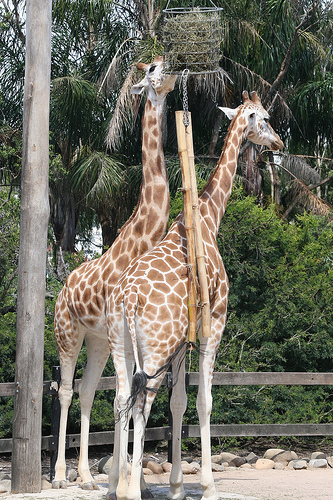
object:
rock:
[263, 448, 285, 460]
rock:
[272, 449, 299, 461]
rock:
[254, 458, 275, 469]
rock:
[293, 459, 308, 469]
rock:
[181, 462, 194, 474]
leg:
[198, 296, 222, 500]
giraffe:
[104, 89, 284, 500]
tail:
[113, 290, 206, 428]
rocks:
[65, 465, 80, 485]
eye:
[264, 117, 270, 123]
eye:
[147, 64, 156, 73]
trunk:
[9, 0, 51, 495]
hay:
[161, 5, 224, 68]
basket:
[162, 6, 224, 73]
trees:
[0, 0, 331, 444]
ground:
[0, 439, 333, 500]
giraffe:
[51, 53, 189, 490]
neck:
[133, 93, 171, 240]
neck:
[174, 133, 247, 236]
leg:
[50, 310, 85, 491]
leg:
[127, 344, 181, 500]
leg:
[111, 372, 137, 500]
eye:
[249, 111, 256, 120]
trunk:
[11, 40, 168, 404]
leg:
[168, 345, 188, 500]